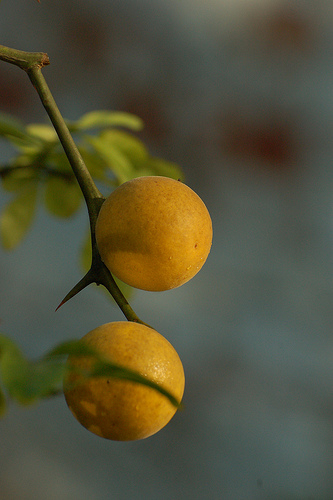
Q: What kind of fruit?
A: Orange.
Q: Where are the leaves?
A: On the branch.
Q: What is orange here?
A: An orange.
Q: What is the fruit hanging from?
A: A branch.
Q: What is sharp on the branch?
A: A thorn.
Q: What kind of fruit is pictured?
A: Oranges.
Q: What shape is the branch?
A: Cylindrical.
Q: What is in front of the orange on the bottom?
A: Leaf.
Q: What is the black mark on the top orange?
A: A shadow.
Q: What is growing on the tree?
A: Oranges.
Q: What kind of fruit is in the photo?
A: Oranges.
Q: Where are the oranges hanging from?
A: A tree.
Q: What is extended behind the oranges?
A: A branch.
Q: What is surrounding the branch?
A: Leaves.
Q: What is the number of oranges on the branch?
A: Two.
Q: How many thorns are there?
A: 1.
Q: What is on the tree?
A: Fruit.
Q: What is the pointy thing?
A: Thorn.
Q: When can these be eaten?
A: When ripe.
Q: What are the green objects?
A: Leaves.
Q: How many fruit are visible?
A: 2.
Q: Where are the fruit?
A: On a tree.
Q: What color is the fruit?
A: Orange.